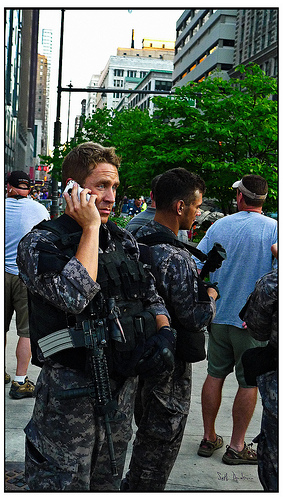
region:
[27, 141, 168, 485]
man talking on cellphone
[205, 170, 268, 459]
man wearing visor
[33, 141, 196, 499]
two men with large guns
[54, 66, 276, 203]
bright green leaves on the trees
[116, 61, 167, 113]
building with green roof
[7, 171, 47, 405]
man wearing a black cap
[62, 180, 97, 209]
silver phone on a man's ear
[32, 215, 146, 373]
bulletproof vest on a man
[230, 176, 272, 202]
visor on a man's head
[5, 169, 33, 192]
black colored baseball hat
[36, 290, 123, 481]
gun belonging to a man on a phone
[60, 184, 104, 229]
right hand holding a phone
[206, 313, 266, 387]
a man's green shorts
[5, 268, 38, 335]
a man's brown shorts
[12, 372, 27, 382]
a man's white colored sock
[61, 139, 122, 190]
light brown hair on a soldier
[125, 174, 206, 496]
THIS IS A SOLDIER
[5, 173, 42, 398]
this is a person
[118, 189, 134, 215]
this is a person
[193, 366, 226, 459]
this is a leg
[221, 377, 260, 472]
this is a leg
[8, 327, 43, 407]
this is a leg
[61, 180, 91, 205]
a white cell phone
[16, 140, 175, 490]
a man talking on a cell phone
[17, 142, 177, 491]
a male soldier standing on street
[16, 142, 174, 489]
a soldier talking on phone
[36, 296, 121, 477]
a large military weapon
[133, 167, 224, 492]
a soldier standing on street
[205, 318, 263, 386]
a pair of green shorts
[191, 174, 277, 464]
a person standing on street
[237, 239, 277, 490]
a soldier standing on street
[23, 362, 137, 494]
a pair of camouflage pants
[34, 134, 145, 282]
soldier on the phone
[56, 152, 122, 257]
soldier on the phone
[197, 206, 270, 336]
the shirt is gray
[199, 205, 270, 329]
the shirt is gray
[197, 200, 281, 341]
the shirt is gray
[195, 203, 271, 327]
the shirt is gray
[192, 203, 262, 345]
the shirt is gray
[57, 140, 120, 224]
A man talking on a cellphone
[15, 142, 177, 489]
A man in fatigues carrying a gun